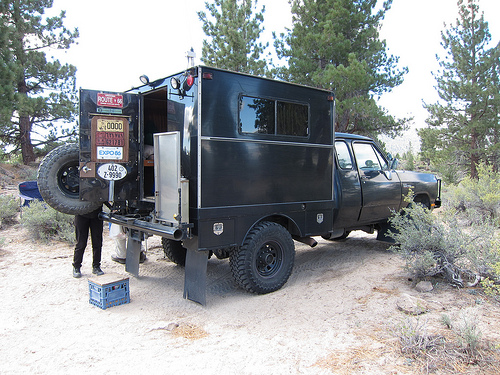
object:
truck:
[78, 65, 440, 306]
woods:
[0, 0, 499, 374]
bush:
[383, 190, 498, 286]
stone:
[394, 291, 430, 314]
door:
[78, 86, 143, 201]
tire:
[35, 142, 103, 216]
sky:
[77, 1, 182, 69]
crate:
[87, 271, 132, 310]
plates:
[95, 93, 125, 108]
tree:
[414, 0, 499, 184]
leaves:
[429, 69, 436, 77]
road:
[1, 220, 499, 374]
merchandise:
[143, 144, 155, 160]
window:
[351, 140, 384, 171]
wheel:
[229, 218, 297, 295]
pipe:
[97, 210, 184, 241]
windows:
[274, 99, 311, 138]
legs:
[72, 214, 90, 278]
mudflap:
[125, 229, 142, 277]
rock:
[413, 279, 433, 292]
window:
[235, 92, 277, 136]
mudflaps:
[182, 236, 210, 307]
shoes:
[72, 265, 84, 279]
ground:
[0, 205, 499, 373]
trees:
[270, 0, 414, 134]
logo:
[102, 164, 124, 179]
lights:
[170, 76, 182, 96]